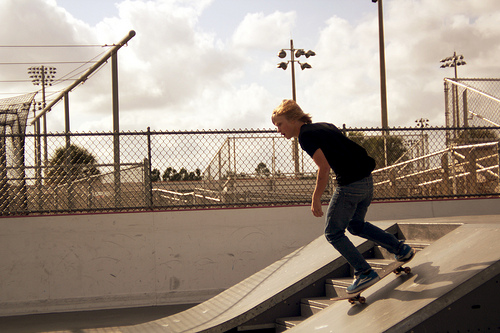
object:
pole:
[289, 39, 300, 175]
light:
[277, 49, 317, 70]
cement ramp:
[105, 206, 500, 333]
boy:
[271, 98, 414, 294]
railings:
[0, 124, 500, 216]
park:
[0, 132, 499, 333]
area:
[237, 175, 309, 202]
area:
[0, 167, 93, 207]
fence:
[202, 134, 430, 195]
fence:
[0, 162, 147, 212]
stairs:
[242, 221, 461, 333]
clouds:
[0, 0, 500, 159]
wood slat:
[328, 247, 417, 302]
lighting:
[27, 65, 58, 86]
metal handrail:
[149, 188, 221, 203]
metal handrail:
[330, 141, 500, 187]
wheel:
[393, 266, 402, 275]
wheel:
[404, 267, 411, 274]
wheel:
[358, 297, 366, 304]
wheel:
[348, 298, 355, 303]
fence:
[0, 125, 500, 217]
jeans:
[323, 175, 412, 275]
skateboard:
[330, 247, 417, 305]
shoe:
[393, 244, 414, 261]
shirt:
[298, 122, 377, 187]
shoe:
[345, 268, 380, 295]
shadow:
[346, 261, 433, 316]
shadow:
[379, 260, 499, 302]